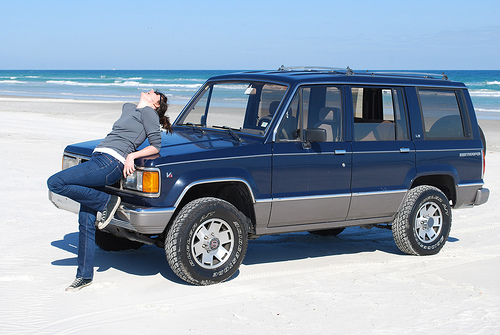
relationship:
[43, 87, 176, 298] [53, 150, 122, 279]
woman wearing jeans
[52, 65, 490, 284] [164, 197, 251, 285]
car has wheel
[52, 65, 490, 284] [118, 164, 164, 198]
car has front light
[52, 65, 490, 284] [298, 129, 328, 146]
car has mirror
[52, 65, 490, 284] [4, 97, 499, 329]
car on beach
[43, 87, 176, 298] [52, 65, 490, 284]
woman leaning on car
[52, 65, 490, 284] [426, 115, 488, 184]
car has spare tire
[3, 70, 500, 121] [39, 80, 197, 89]
water has foam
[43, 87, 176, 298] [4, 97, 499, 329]
woman on beach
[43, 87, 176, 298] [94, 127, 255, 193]
woman leaning on hood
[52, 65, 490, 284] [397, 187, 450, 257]
car has wheel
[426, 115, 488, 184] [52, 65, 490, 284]
spare tire on car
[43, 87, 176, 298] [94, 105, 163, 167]
woman wearing hood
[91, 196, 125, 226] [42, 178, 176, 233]
shoe on bumper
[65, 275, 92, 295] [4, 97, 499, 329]
shoe on beach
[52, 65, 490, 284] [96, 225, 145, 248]
car has wheel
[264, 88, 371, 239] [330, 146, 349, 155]
door has handle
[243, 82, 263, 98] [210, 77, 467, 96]
mirror on ceiling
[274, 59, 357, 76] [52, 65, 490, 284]
roof rack on car